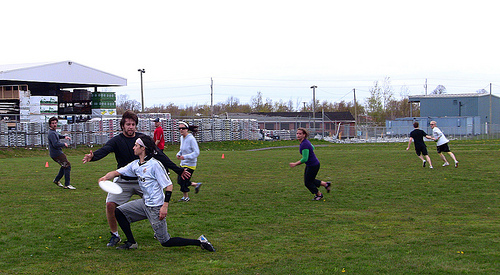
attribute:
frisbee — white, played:
[76, 170, 133, 202]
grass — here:
[244, 194, 317, 239]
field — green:
[46, 147, 490, 247]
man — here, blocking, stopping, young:
[426, 118, 472, 174]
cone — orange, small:
[216, 149, 236, 168]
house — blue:
[379, 81, 490, 161]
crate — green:
[91, 91, 121, 102]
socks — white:
[153, 228, 209, 257]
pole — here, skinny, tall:
[137, 76, 154, 111]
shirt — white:
[126, 164, 168, 209]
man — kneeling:
[122, 150, 182, 211]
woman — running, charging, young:
[163, 115, 207, 196]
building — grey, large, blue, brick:
[411, 98, 468, 158]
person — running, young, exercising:
[277, 126, 364, 250]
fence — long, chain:
[197, 114, 376, 143]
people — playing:
[71, 103, 351, 251]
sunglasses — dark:
[177, 125, 190, 134]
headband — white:
[171, 117, 198, 130]